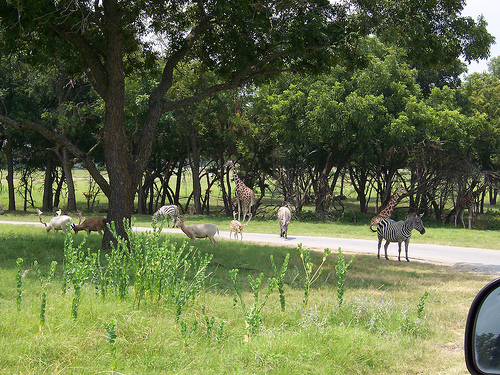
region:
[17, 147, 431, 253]
herd of different animals on path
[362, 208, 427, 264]
zebra walking down path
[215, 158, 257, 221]
giraffe standing among trees in background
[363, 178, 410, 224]
giraffe sitting under trees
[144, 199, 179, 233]
zebra searching ground in the background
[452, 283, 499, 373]
sideview mirror of car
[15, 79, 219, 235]
tree trunk in the foreground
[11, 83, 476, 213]
stand of trees in the background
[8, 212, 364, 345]
weeds growing in grass in foreground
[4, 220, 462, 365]
grass in the foreground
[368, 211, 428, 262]
a zebra standing in grass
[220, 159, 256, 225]
a giraffe standing in grass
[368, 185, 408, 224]
a giraffe seated in grass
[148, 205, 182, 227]
a zebra standing in grass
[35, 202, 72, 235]
a white elk standing in grass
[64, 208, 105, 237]
a white elk standing in grass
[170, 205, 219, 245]
a white elk standing in grass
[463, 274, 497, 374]
a car rear view mirror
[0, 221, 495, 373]
a patch of green grass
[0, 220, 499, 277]
a paved roadway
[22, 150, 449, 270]
zebra, giraffe, antelope, deer hanging out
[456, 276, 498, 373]
1/2 a car's side mirror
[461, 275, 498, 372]
side mirror is black, reflection is dark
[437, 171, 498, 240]
giraffe wandering in the shade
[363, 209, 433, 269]
zebra wandering down a paved road in the same direction, more or less, as giraffe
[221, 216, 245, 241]
dik dik, probably, it's really small, but not miniature, & it's a deer, meandering the same road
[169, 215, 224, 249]
so help me, this looks like a white tailed deer but it's probably an antelope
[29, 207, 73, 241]
then again, this one really looks like it has antlers. not horns. antlers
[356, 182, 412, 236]
giraffe, in shade, beneath tree, lounging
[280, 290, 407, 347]
lavender flowers on little obviously edible plants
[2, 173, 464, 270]
African animals on a road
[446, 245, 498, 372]
Car side mirror by road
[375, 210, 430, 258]
a zebra in the field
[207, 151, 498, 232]
Three giraffes in the field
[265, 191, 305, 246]
A zebra walking towards the car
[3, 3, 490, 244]
A tall tree providing shade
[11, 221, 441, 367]
Tall grasses provide food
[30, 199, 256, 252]
Horned animals eating in field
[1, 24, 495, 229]
shorter trees providing shade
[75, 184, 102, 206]
an animal in the field in the background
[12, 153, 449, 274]
a group of different types of animals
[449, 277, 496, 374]
edge of a sideview mirror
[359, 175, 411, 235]
giraffe laying in the grass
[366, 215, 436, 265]
zebra walking along the path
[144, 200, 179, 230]
black and white zebra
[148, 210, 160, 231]
head bent down towards the ground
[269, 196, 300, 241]
animal crossing the road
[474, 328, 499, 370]
reflection in the mirror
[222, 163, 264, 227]
giraffe standing on the grass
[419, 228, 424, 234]
black snout